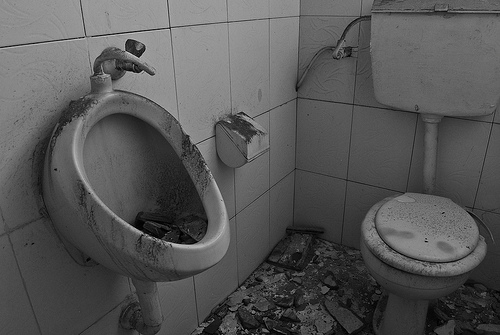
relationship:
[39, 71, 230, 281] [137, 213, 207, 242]
urinal has rocks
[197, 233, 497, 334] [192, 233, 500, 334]
debris on floor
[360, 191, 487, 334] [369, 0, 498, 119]
toilet has tank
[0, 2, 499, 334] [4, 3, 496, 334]
wall has tile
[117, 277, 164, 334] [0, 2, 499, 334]
pipe through wall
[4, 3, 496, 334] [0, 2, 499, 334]
tile on wall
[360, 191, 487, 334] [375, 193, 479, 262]
toilet has cover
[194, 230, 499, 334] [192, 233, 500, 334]
tile on floor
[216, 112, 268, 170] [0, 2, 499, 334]
holder on wall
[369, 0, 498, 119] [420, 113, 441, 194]
tank has pipe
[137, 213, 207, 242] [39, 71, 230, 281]
bricks in urinal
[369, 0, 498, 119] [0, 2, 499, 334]
tank on wall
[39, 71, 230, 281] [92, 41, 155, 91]
urinal has hose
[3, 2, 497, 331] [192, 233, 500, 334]
bathroom has floor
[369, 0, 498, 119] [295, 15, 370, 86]
tank has hose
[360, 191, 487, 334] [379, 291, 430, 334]
toilet has base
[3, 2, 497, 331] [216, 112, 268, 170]
bathroom has holder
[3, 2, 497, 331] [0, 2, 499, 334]
bathroom has wall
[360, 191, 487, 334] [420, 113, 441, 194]
toilet has pipe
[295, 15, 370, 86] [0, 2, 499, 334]
hose on wall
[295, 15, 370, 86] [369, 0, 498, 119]
hose to tank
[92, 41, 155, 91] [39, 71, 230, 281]
hose on urinal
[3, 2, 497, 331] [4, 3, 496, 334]
bathroom has tile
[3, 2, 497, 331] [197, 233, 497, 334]
bathroom has debris